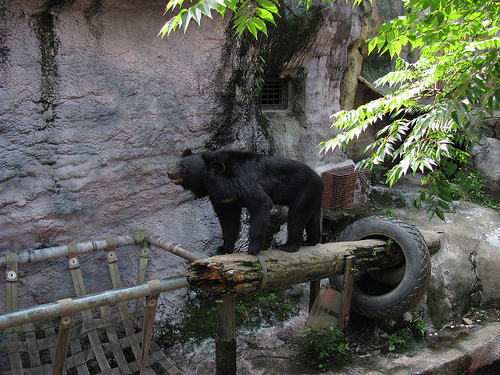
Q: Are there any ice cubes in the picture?
A: No, there are no ice cubes.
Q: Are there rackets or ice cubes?
A: No, there are no ice cubes or rackets.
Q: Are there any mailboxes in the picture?
A: No, there are no mailboxes.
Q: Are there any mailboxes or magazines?
A: No, there are no mailboxes or magazines.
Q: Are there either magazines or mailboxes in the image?
A: No, there are no mailboxes or magazines.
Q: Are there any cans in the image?
A: No, there are no cans.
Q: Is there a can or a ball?
A: No, there are no cans or balls.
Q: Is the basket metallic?
A: Yes, the basket is metallic.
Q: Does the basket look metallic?
A: Yes, the basket is metallic.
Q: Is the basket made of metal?
A: Yes, the basket is made of metal.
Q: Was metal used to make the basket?
A: Yes, the basket is made of metal.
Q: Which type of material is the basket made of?
A: The basket is made of metal.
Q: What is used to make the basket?
A: The basket is made of metal.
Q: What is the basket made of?
A: The basket is made of metal.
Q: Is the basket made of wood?
A: No, the basket is made of metal.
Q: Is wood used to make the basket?
A: No, the basket is made of metal.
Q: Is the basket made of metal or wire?
A: The basket is made of metal.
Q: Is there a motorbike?
A: No, there are no motorcycles.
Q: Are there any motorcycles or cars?
A: No, there are no motorcycles or cars.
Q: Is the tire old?
A: Yes, the tire is old.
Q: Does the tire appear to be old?
A: Yes, the tire is old.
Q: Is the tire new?
A: No, the tire is old.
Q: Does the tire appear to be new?
A: No, the tire is old.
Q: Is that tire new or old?
A: The tire is old.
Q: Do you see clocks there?
A: No, there are no clocks.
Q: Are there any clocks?
A: No, there are no clocks.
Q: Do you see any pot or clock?
A: No, there are no clocks or pots.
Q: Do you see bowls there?
A: No, there are no bowls.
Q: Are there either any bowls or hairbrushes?
A: No, there are no bowls or hairbrushes.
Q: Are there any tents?
A: No, there are no tents.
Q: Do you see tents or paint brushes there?
A: No, there are no tents or paint brushes.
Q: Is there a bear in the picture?
A: Yes, there is a bear.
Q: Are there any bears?
A: Yes, there is a bear.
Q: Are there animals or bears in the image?
A: Yes, there is a bear.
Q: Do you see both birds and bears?
A: No, there is a bear but no birds.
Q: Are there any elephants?
A: No, there are no elephants.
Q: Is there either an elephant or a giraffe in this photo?
A: No, there are no elephants or giraffes.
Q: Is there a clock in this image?
A: No, there are no clocks.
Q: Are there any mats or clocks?
A: No, there are no clocks or mats.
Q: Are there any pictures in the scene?
A: No, there are no pictures.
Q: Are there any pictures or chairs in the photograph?
A: No, there are no pictures or chairs.